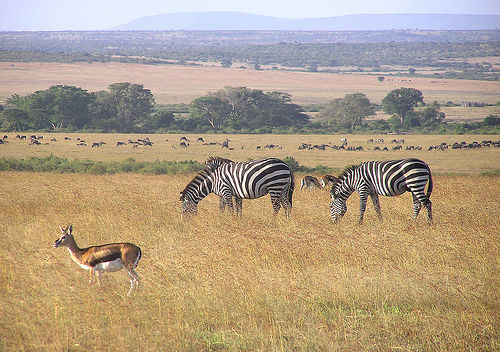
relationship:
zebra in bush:
[173, 154, 298, 225] [0, 81, 497, 348]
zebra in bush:
[327, 155, 435, 226] [0, 81, 497, 348]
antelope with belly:
[49, 229, 145, 299] [93, 256, 126, 277]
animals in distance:
[0, 124, 499, 154] [4, 0, 499, 154]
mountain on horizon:
[121, 10, 499, 31] [2, 4, 499, 63]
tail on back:
[424, 165, 434, 207] [406, 162, 430, 189]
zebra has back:
[327, 155, 435, 226] [406, 162, 430, 189]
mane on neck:
[185, 153, 231, 196] [191, 164, 226, 202]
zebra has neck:
[173, 154, 298, 225] [191, 164, 226, 202]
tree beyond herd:
[182, 83, 313, 137] [0, 124, 499, 154]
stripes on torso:
[191, 157, 296, 204] [192, 161, 292, 205]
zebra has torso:
[173, 154, 298, 225] [192, 161, 292, 205]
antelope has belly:
[49, 222, 146, 299] [96, 256, 126, 276]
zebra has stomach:
[173, 154, 298, 225] [231, 184, 273, 200]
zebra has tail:
[327, 155, 435, 226] [424, 165, 434, 207]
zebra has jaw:
[173, 154, 298, 225] [188, 200, 196, 217]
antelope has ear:
[49, 222, 146, 299] [64, 226, 75, 236]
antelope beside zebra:
[49, 222, 146, 299] [173, 154, 298, 225]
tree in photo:
[182, 83, 313, 137] [2, 5, 496, 343]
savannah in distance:
[3, 29, 499, 62] [4, 0, 499, 154]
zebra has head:
[173, 154, 298, 225] [178, 189, 200, 224]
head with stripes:
[178, 189, 200, 224] [182, 192, 197, 221]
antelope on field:
[49, 222, 146, 299] [4, 134, 499, 349]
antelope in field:
[49, 222, 146, 299] [4, 134, 499, 349]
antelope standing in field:
[49, 222, 146, 299] [4, 134, 499, 349]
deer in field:
[301, 172, 326, 195] [4, 134, 499, 349]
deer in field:
[322, 169, 338, 193] [4, 134, 499, 349]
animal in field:
[173, 154, 298, 225] [4, 134, 499, 349]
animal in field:
[327, 155, 435, 226] [4, 134, 499, 349]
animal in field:
[49, 229, 145, 299] [4, 134, 499, 349]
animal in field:
[301, 172, 326, 195] [4, 134, 499, 349]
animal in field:
[322, 169, 338, 193] [4, 134, 499, 349]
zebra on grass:
[173, 154, 298, 225] [1, 169, 500, 345]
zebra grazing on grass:
[173, 154, 298, 225] [1, 169, 500, 345]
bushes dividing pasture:
[1, 76, 496, 137] [2, 46, 498, 342]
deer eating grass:
[301, 172, 326, 195] [1, 169, 500, 345]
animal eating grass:
[320, 171, 340, 189] [1, 169, 500, 345]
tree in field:
[182, 83, 313, 137] [0, 131, 499, 349]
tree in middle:
[182, 83, 313, 137] [4, 82, 499, 176]